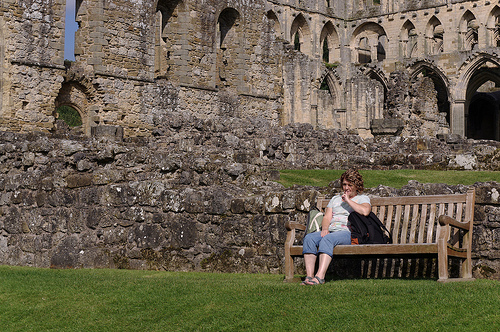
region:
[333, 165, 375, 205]
the head of a woman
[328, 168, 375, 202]
the eyes of a woman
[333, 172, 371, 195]
the nose of a woman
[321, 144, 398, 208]
the hair of a woman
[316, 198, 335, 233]
the arm of a woman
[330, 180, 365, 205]
the hand of a woman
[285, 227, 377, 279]
the legs of a woman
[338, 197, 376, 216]
the elbow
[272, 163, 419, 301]
a woman sitting on a bench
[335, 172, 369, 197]
head of a person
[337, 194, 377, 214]
arm of a person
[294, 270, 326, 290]
feet of a person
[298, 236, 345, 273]
leg of a person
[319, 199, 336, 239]
arm of a person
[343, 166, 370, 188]
hair of a person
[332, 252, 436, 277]
shadows underneath bench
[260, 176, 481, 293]
a wooden bench on grass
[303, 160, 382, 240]
woman wearing a shirt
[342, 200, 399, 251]
a bag on a bench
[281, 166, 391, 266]
A lady sitting on the bench.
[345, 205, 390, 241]
A black backpack next to the lady.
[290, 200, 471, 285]
The bench is on the lawn.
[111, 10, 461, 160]
A old rock building behind the lady.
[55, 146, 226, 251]
The wall is rocks.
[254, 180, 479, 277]
The bench is wooden.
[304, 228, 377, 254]
The lady is wearing blue capris.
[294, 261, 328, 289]
The lady is wearing sandals.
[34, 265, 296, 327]
The grass is green.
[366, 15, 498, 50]
Arch open window on the building.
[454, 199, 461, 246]
brown wooden bench board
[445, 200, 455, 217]
brown wooden bench board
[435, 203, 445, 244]
brown wooden bench board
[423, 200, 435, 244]
brown wooden bench board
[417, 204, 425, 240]
brown wooden bench board